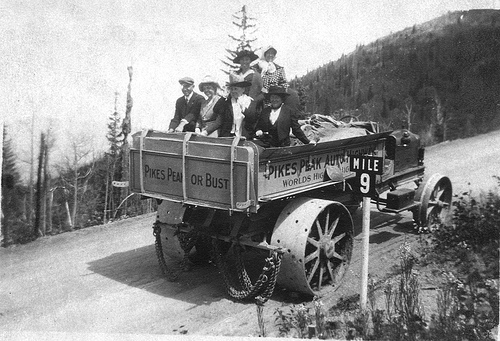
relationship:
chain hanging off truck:
[211, 239, 282, 307] [130, 111, 450, 300]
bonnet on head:
[260, 46, 281, 61] [228, 44, 268, 97]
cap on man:
[195, 73, 222, 89] [161, 66, 202, 133]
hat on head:
[264, 82, 291, 100] [260, 82, 294, 112]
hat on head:
[226, 68, 254, 85] [225, 82, 247, 95]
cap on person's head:
[198, 75, 222, 93] [197, 72, 224, 99]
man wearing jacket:
[153, 72, 204, 137] [171, 93, 207, 130]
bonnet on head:
[232, 49, 260, 63] [238, 56, 250, 66]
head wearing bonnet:
[257, 32, 287, 72] [259, 40, 279, 54]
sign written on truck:
[132, 149, 248, 196] [130, 111, 450, 300]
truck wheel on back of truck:
[268, 194, 354, 297] [130, 111, 450, 300]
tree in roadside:
[0, 118, 26, 245] [0, 126, 499, 338]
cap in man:
[170, 71, 199, 86] [172, 78, 208, 128]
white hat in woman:
[195, 67, 222, 88] [196, 74, 233, 141]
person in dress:
[260, 44, 289, 90] [254, 60, 292, 92]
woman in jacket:
[252, 85, 316, 147] [253, 102, 308, 146]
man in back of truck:
[165, 77, 206, 134] [130, 111, 450, 300]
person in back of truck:
[251, 88, 314, 147] [130, 111, 450, 300]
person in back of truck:
[219, 75, 258, 139] [130, 111, 450, 300]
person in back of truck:
[195, 80, 232, 139] [130, 111, 450, 300]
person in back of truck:
[230, 50, 263, 100] [130, 111, 450, 300]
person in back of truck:
[260, 44, 289, 90] [130, 111, 450, 300]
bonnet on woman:
[232, 49, 260, 63] [229, 47, 258, 97]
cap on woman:
[198, 75, 222, 93] [194, 76, 230, 139]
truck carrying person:
[134, 120, 464, 304] [254, 85, 317, 147]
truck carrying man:
[134, 120, 464, 304] [173, 71, 203, 131]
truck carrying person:
[134, 120, 464, 304] [212, 73, 258, 137]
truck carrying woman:
[134, 120, 464, 304] [260, 40, 281, 101]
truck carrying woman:
[134, 120, 464, 304] [225, 47, 259, 98]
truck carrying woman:
[134, 120, 464, 304] [195, 76, 225, 137]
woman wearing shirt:
[248, 87, 301, 152] [270, 103, 282, 129]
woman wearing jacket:
[248, 87, 301, 152] [255, 95, 295, 145]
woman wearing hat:
[248, 87, 301, 152] [263, 85, 291, 99]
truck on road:
[129, 115, 453, 299] [25, 144, 497, 334]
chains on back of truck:
[199, 240, 283, 306] [123, 102, 472, 317]